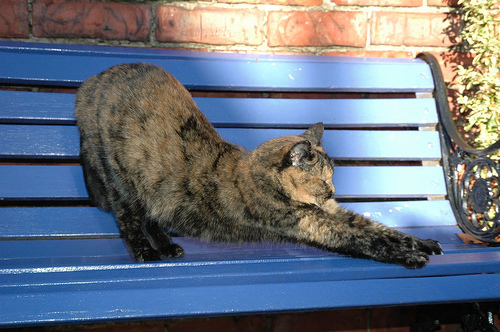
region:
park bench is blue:
[0, 37, 499, 322]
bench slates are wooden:
[0, 43, 498, 323]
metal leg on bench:
[411, 48, 498, 330]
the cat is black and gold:
[77, 64, 443, 269]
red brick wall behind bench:
[1, 1, 499, 331]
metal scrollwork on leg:
[446, 154, 498, 241]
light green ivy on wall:
[443, 2, 498, 232]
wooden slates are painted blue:
[1, 40, 497, 323]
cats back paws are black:
[110, 202, 189, 263]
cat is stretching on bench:
[73, 63, 443, 267]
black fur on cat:
[172, 102, 193, 147]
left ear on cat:
[276, 131, 306, 171]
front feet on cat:
[122, 238, 191, 264]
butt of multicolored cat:
[68, 87, 98, 132]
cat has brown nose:
[326, 177, 334, 193]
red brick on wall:
[201, 17, 254, 39]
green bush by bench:
[457, 25, 493, 87]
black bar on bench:
[440, 119, 472, 162]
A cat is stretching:
[70, 59, 446, 272]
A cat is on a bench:
[2, 38, 498, 330]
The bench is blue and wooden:
[3, 33, 499, 328]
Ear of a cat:
[283, 135, 317, 169]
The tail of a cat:
[73, 70, 114, 216]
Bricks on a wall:
[2, 2, 458, 56]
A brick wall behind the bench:
[3, 3, 499, 330]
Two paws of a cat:
[388, 223, 449, 278]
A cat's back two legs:
[108, 190, 192, 268]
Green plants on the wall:
[441, 2, 497, 148]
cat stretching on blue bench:
[71, 65, 439, 287]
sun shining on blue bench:
[238, 48, 455, 222]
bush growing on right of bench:
[440, 10, 498, 184]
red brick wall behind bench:
[24, 7, 496, 79]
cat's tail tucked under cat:
[68, 140, 123, 221]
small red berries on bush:
[445, 47, 480, 69]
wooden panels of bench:
[7, 97, 429, 113]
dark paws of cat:
[101, 222, 182, 264]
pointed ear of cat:
[279, 140, 308, 165]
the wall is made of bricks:
[289, 10, 422, 57]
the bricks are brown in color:
[289, 15, 426, 50]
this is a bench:
[12, 42, 72, 314]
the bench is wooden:
[14, 171, 87, 313]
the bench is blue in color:
[9, 164, 74, 323]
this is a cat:
[66, 70, 461, 260]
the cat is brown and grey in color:
[125, 118, 200, 176]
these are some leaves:
[466, 14, 496, 117]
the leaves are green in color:
[470, 17, 496, 71]